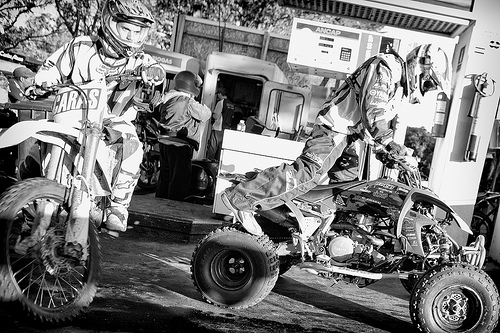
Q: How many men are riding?
A: Two.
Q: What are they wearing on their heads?
A: Helmets.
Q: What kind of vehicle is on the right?
A: Four wheeler.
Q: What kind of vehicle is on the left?
A: Dirtbike.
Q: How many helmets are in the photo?
A: Three.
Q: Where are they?
A: At a gas station.